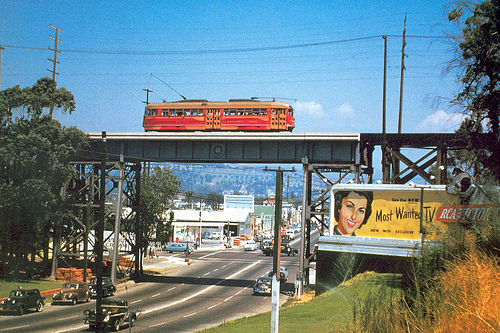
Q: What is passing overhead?
A: A train.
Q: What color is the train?
A: Red.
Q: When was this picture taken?
A: During the day.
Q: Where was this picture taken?
A: In the city.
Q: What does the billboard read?
A: Most wanted TV.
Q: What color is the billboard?
A: Yellow.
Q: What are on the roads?
A: Cars.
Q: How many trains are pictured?
A: One.